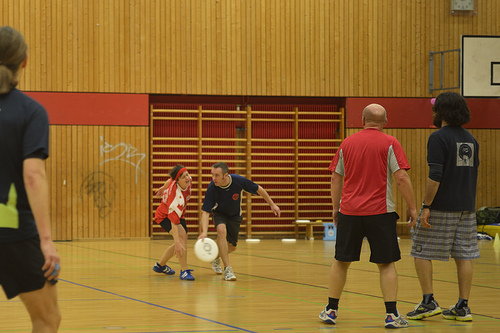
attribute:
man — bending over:
[191, 159, 286, 283]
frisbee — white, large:
[193, 236, 220, 263]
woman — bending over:
[149, 163, 195, 284]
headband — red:
[172, 165, 190, 180]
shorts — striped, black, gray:
[408, 204, 482, 264]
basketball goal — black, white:
[457, 31, 499, 97]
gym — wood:
[1, 0, 499, 332]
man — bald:
[317, 103, 420, 332]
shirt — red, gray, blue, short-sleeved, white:
[328, 124, 410, 215]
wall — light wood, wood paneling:
[0, 0, 499, 243]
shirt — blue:
[198, 174, 258, 220]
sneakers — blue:
[149, 258, 201, 284]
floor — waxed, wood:
[1, 240, 500, 333]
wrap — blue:
[53, 263, 58, 276]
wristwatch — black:
[421, 202, 432, 211]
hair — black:
[434, 91, 471, 126]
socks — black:
[327, 293, 401, 313]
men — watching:
[309, 89, 482, 326]